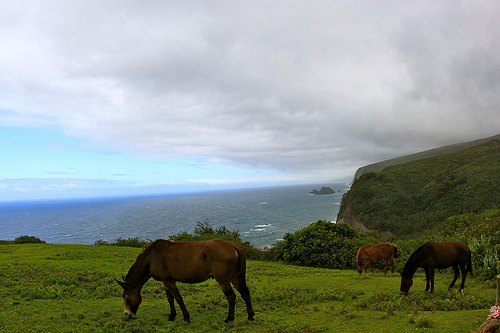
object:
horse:
[399, 239, 475, 295]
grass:
[0, 254, 77, 332]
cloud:
[1, 0, 499, 179]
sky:
[1, 0, 500, 202]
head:
[397, 270, 414, 295]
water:
[0, 181, 351, 249]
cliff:
[334, 133, 499, 241]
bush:
[259, 218, 393, 269]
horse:
[114, 238, 257, 323]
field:
[1, 242, 500, 331]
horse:
[351, 242, 399, 275]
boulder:
[309, 186, 334, 195]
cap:
[253, 222, 274, 231]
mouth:
[123, 308, 136, 318]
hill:
[1, 206, 499, 332]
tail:
[467, 249, 474, 276]